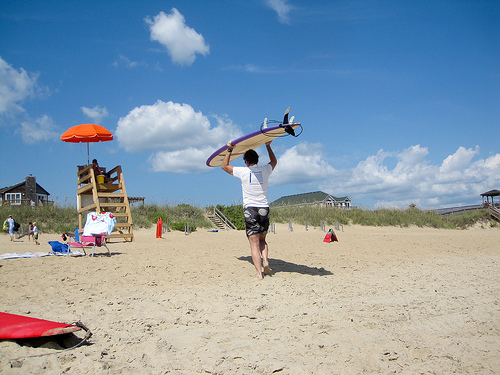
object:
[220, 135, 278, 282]
man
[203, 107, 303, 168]
surfboard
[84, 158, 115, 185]
lifeguard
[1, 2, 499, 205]
sky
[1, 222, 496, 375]
ground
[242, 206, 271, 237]
shorts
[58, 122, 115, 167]
umbrella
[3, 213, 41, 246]
family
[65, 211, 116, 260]
chair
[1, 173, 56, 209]
house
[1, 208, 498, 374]
beach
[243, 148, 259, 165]
hair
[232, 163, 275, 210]
shirt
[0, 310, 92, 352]
surfboard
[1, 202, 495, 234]
grass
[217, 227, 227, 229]
steps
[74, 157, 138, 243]
chair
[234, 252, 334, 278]
shadow